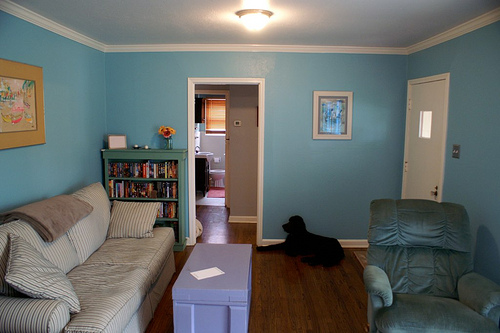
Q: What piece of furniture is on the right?
A: A cushioned chair.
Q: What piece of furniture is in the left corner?
A: A bookshelf.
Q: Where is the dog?
A: Lying on the floor.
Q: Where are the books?
A: In the boocase.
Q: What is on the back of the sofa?
A: A blanket.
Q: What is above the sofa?
A: A picture.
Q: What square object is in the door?
A: A glass window.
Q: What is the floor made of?
A: Wood.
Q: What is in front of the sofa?
A: A coffee table.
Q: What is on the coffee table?
A: A sheet of paper.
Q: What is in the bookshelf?
A: Books.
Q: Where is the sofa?
A: Against the left wall.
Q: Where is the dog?
A: Lying on the floor.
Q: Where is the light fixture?
A: On the ceiling.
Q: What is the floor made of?
A: Wood.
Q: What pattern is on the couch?
A: Stripes.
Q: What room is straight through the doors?
A: The bathroom.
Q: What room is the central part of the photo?
A: The living room.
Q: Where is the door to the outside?
A: On the right.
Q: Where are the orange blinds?
A: On the bathroom window.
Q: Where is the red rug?
A: On the bathroom floor.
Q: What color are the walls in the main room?
A: Blue.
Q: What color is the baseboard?
A: White.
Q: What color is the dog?
A: Black.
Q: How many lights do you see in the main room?
A: 1.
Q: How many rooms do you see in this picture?
A: 2.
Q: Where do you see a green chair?
A: Front right of the picture.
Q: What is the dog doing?
A: Laying down.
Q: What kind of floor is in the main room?
A: Hardwood.